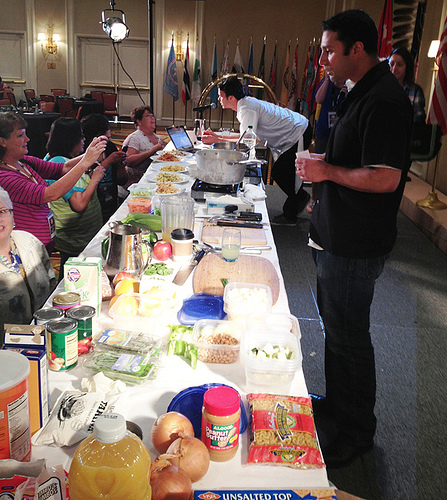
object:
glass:
[220, 225, 241, 263]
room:
[4, 3, 446, 488]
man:
[293, 8, 411, 468]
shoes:
[312, 410, 374, 463]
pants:
[312, 243, 389, 438]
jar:
[203, 385, 242, 462]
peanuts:
[201, 408, 243, 462]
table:
[1, 131, 330, 499]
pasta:
[246, 393, 323, 470]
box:
[194, 488, 336, 499]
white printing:
[222, 492, 294, 500]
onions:
[151, 410, 209, 499]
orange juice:
[68, 413, 152, 499]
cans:
[43, 310, 82, 365]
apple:
[154, 240, 172, 262]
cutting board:
[192, 251, 280, 306]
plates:
[143, 148, 194, 197]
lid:
[204, 386, 242, 416]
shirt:
[305, 60, 413, 254]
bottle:
[68, 411, 153, 499]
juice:
[223, 245, 240, 260]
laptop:
[166, 125, 201, 154]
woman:
[0, 112, 108, 255]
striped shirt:
[0, 153, 64, 252]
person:
[217, 76, 314, 225]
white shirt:
[237, 96, 308, 162]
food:
[33, 291, 99, 371]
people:
[0, 8, 427, 498]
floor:
[261, 162, 446, 499]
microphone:
[193, 103, 216, 134]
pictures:
[89, 135, 110, 185]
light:
[104, 17, 129, 43]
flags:
[165, 30, 321, 128]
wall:
[1, 1, 346, 129]